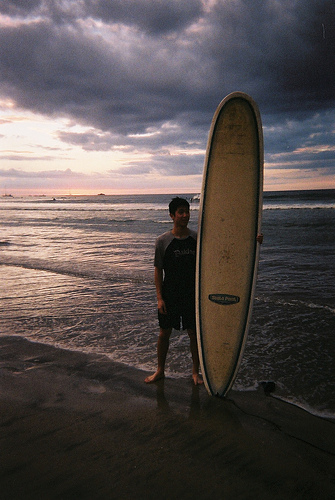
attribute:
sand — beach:
[0, 331, 333, 498]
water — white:
[40, 193, 164, 289]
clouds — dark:
[0, 1, 327, 177]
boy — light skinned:
[81, 156, 224, 320]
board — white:
[187, 88, 275, 403]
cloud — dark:
[2, 4, 324, 158]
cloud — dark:
[52, 123, 333, 172]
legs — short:
[156, 334, 196, 369]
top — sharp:
[211, 86, 265, 137]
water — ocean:
[4, 190, 324, 380]